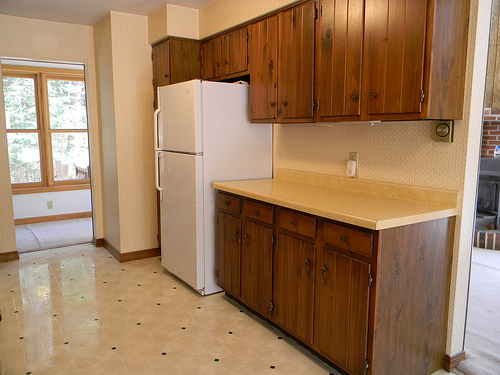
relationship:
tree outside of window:
[6, 78, 84, 182] [3, 76, 89, 183]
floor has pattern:
[1, 243, 462, 373] [115, 277, 166, 335]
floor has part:
[1, 243, 462, 373] [13, 331, 31, 345]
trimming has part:
[91, 237, 162, 264] [95, 237, 105, 247]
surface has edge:
[209, 176, 447, 235] [375, 199, 461, 233]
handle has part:
[343, 89, 359, 104] [353, 92, 358, 101]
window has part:
[3, 76, 89, 183] [48, 80, 88, 132]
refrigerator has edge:
[151, 78, 277, 299] [191, 76, 205, 296]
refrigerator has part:
[151, 78, 277, 299] [150, 85, 165, 154]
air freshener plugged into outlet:
[343, 161, 357, 179] [344, 148, 360, 179]